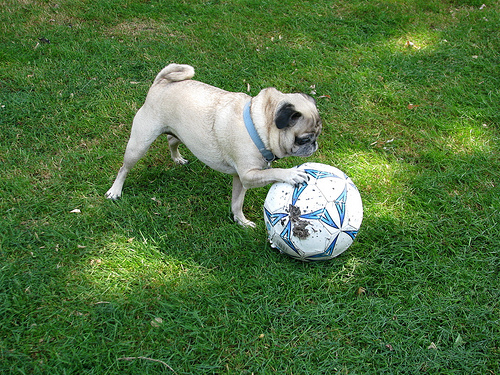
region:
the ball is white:
[274, 158, 384, 275]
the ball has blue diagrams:
[269, 161, 363, 267]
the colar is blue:
[239, 112, 269, 152]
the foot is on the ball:
[234, 167, 316, 195]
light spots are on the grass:
[359, 134, 415, 212]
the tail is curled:
[172, 60, 199, 84]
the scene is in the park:
[12, 6, 486, 373]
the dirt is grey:
[266, 198, 321, 260]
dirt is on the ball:
[279, 196, 324, 240]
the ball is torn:
[255, 232, 303, 259]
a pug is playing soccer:
[106, 50, 365, 270]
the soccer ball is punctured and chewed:
[258, 160, 363, 262]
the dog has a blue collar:
[238, 84, 279, 165]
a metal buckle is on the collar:
[256, 142, 280, 165]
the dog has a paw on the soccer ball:
[232, 148, 322, 198]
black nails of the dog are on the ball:
[286, 165, 313, 193]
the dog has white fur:
[103, 59, 322, 238]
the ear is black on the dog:
[271, 101, 306, 131]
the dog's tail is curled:
[148, 50, 202, 95]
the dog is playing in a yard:
[21, 13, 483, 361]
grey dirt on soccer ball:
[273, 196, 345, 256]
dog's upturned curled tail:
[156, 41, 204, 88]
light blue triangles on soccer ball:
[331, 190, 355, 229]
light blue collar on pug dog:
[238, 95, 278, 166]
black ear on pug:
[274, 101, 305, 136]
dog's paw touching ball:
[249, 155, 325, 202]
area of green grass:
[361, 271, 443, 371]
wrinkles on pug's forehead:
[307, 112, 323, 137]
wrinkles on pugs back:
[218, 97, 245, 127]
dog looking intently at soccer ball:
[295, 128, 345, 158]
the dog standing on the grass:
[106, 59, 322, 231]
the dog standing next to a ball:
[102, 55, 324, 225]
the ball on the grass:
[260, 163, 362, 262]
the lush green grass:
[0, 3, 495, 373]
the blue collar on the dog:
[243, 100, 272, 160]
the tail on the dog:
[153, 61, 193, 83]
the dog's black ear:
[275, 103, 297, 130]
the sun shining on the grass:
[91, 240, 189, 292]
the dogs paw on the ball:
[269, 160, 311, 194]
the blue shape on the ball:
[333, 180, 351, 224]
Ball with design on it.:
[260, 160, 375, 260]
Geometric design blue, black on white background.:
[256, 160, 372, 260]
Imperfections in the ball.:
[254, 159, 366, 261]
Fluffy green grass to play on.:
[26, 20, 473, 337]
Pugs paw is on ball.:
[93, 37, 378, 280]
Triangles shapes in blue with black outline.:
[259, 158, 374, 271]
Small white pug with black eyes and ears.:
[109, 53, 329, 229]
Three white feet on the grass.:
[91, 57, 331, 243]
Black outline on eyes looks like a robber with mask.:
[100, 63, 335, 246]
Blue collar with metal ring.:
[101, 59, 327, 239]